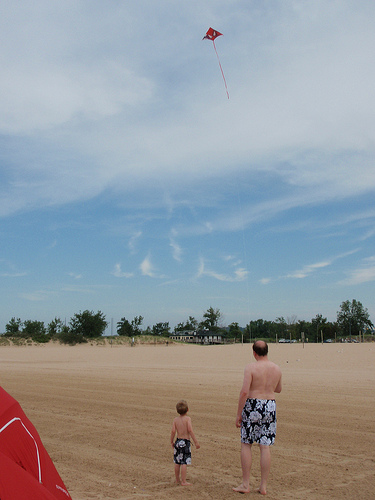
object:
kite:
[201, 26, 229, 99]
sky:
[0, 1, 374, 336]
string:
[211, 39, 229, 99]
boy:
[170, 399, 200, 486]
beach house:
[169, 326, 225, 344]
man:
[232, 339, 282, 495]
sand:
[0, 343, 375, 500]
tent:
[0, 387, 70, 500]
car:
[279, 339, 285, 343]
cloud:
[0, 0, 374, 172]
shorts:
[240, 398, 276, 445]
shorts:
[173, 438, 191, 465]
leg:
[232, 443, 252, 493]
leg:
[254, 443, 271, 494]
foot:
[232, 484, 250, 493]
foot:
[255, 486, 267, 495]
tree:
[74, 309, 109, 337]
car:
[326, 339, 332, 343]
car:
[291, 339, 297, 343]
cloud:
[109, 195, 374, 295]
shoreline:
[0, 315, 374, 349]